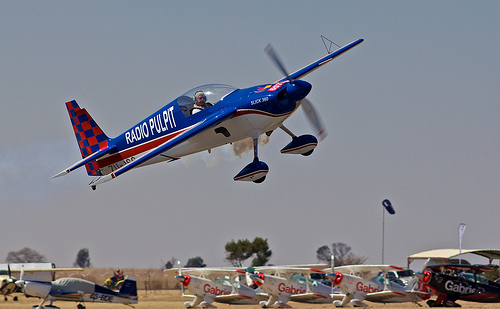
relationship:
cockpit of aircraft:
[168, 77, 239, 121] [53, 29, 367, 202]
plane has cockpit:
[84, 44, 371, 205] [182, 71, 320, 152]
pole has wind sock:
[379, 206, 391, 265] [375, 187, 405, 211]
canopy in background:
[412, 247, 488, 270] [0, 199, 499, 234]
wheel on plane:
[236, 157, 270, 189] [59, 44, 343, 201]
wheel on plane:
[278, 123, 320, 167] [59, 44, 343, 201]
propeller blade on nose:
[257, 35, 297, 86] [249, 79, 319, 124]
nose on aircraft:
[249, 79, 319, 124] [53, 29, 367, 202]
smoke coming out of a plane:
[218, 131, 276, 163] [26, 13, 440, 244]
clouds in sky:
[403, 95, 459, 152] [57, 2, 469, 243]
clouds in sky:
[0, 0, 473, 251] [0, 0, 494, 263]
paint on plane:
[216, 87, 253, 121] [53, 125, 327, 254]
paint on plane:
[141, 86, 271, 158] [51, 35, 366, 188]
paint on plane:
[141, 86, 271, 158] [52, 70, 342, 186]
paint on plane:
[141, 86, 271, 158] [49, 70, 333, 236]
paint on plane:
[141, 86, 271, 158] [43, 27, 373, 197]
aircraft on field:
[0, 249, 500, 309] [0, 254, 500, 309]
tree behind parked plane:
[213, 234, 280, 263] [169, 259, 261, 307]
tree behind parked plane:
[213, 234, 280, 263] [233, 254, 308, 306]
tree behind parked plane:
[213, 234, 280, 263] [299, 261, 406, 306]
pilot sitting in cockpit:
[190, 88, 214, 116] [178, 75, 238, 119]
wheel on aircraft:
[253, 175, 267, 183] [51, 34, 365, 190]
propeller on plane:
[245, 30, 341, 152] [38, 32, 398, 211]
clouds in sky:
[123, 200, 204, 260] [0, 0, 494, 263]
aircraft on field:
[64, 54, 336, 188] [3, 254, 495, 305]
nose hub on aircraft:
[276, 74, 321, 106] [59, 30, 430, 244]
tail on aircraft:
[52, 98, 114, 170] [52, 35, 364, 183]